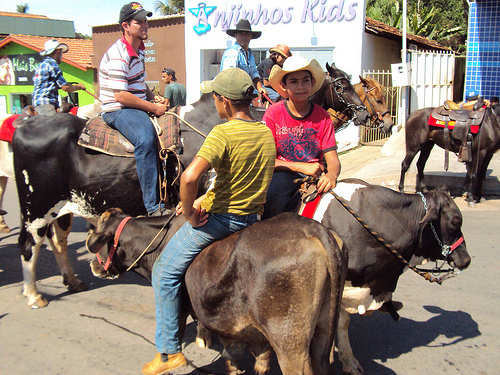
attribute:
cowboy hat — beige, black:
[267, 52, 329, 99]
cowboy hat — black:
[224, 16, 265, 41]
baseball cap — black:
[118, 0, 155, 29]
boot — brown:
[137, 339, 194, 374]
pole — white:
[397, 2, 414, 154]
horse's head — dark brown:
[319, 61, 370, 127]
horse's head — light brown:
[356, 71, 398, 132]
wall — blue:
[459, 3, 500, 100]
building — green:
[2, 34, 101, 113]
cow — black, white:
[13, 92, 224, 299]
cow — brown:
[87, 205, 353, 373]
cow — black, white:
[234, 177, 473, 365]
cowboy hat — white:
[38, 37, 70, 59]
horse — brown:
[396, 95, 496, 203]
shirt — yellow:
[202, 115, 277, 218]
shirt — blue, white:
[30, 58, 71, 109]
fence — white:
[365, 65, 403, 145]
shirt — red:
[262, 101, 339, 170]